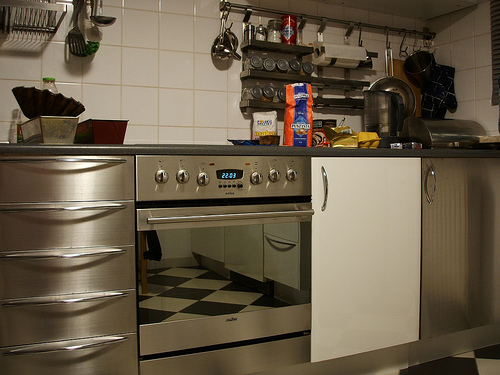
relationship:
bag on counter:
[283, 83, 314, 148] [0, 141, 500, 162]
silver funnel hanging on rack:
[211, 32, 243, 63] [220, 0, 434, 45]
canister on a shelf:
[256, 0, 337, 45] [255, 59, 339, 97]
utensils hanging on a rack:
[71, 2, 111, 64] [220, 4, 440, 39]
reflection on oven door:
[141, 255, 273, 331] [168, 270, 238, 308]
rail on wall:
[219, 0, 435, 41] [1, 0, 433, 145]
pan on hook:
[371, 72, 425, 127] [393, 28, 425, 65]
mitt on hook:
[421, 62, 458, 122] [416, 34, 441, 57]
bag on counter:
[281, 80, 314, 150] [233, 135, 455, 205]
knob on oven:
[287, 169, 298, 183] [135, 155, 311, 233]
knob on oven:
[268, 168, 280, 181] [135, 155, 311, 233]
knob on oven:
[248, 170, 264, 184] [135, 155, 311, 233]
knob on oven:
[197, 170, 209, 185] [135, 155, 311, 233]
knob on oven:
[175, 168, 189, 182] [135, 155, 311, 233]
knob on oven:
[155, 168, 168, 184] [135, 155, 311, 233]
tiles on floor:
[385, 341, 498, 372] [416, 314, 498, 371]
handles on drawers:
[0, 247, 126, 260] [0, 153, 137, 373]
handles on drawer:
[0, 154, 126, 165] [0, 153, 135, 204]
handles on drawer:
[0, 335, 128, 357] [0, 330, 140, 373]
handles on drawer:
[0, 290, 130, 308] [0, 289, 140, 348]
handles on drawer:
[1, 203, 126, 213] [1, 200, 134, 253]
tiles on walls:
[2, 3, 484, 144] [1, 1, 499, 144]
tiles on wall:
[2, 3, 484, 144] [1, 0, 433, 145]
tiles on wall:
[2, 3, 484, 144] [430, 0, 499, 139]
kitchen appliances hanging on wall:
[208, 1, 462, 118] [60, 2, 242, 139]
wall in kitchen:
[104, 35, 196, 77] [2, 4, 484, 358]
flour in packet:
[253, 111, 271, 131] [242, 100, 285, 148]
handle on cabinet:
[318, 166, 330, 213] [309, 156, 420, 362]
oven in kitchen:
[120, 134, 364, 361] [2, 4, 484, 358]